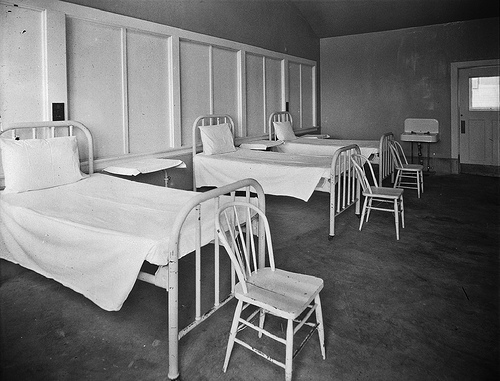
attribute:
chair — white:
[216, 204, 327, 379]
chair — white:
[349, 149, 409, 240]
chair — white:
[386, 137, 431, 198]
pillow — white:
[1, 132, 81, 187]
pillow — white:
[195, 122, 247, 157]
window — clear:
[464, 77, 499, 110]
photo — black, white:
[3, 6, 497, 369]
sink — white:
[401, 100, 461, 171]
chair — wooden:
[209, 205, 342, 379]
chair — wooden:
[343, 148, 410, 238]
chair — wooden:
[384, 138, 427, 201]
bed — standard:
[2, 119, 269, 379]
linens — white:
[5, 146, 255, 318]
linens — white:
[188, 127, 336, 204]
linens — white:
[275, 127, 389, 169]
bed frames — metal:
[2, 112, 395, 379]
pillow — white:
[3, 132, 85, 196]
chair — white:
[336, 144, 409, 253]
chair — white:
[212, 197, 332, 378]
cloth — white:
[85, 148, 186, 178]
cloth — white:
[235, 135, 281, 151]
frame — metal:
[154, 220, 247, 313]